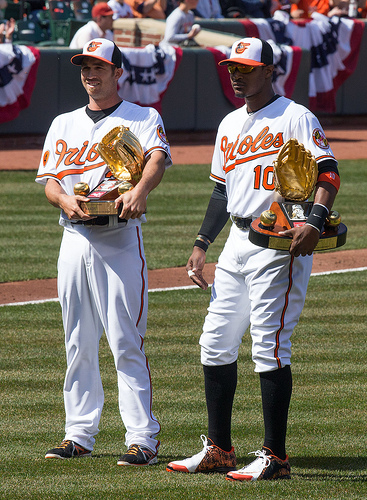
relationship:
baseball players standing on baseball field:
[33, 33, 170, 467] [4, 126, 365, 495]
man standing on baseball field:
[181, 33, 341, 482] [4, 126, 365, 495]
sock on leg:
[255, 365, 295, 454] [229, 279, 303, 481]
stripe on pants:
[139, 374, 166, 460] [60, 226, 149, 442]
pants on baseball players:
[60, 226, 149, 442] [33, 33, 170, 467]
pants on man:
[196, 218, 312, 374] [181, 33, 341, 482]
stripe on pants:
[272, 254, 296, 369] [196, 218, 312, 374]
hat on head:
[214, 35, 274, 70] [216, 37, 280, 107]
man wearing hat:
[181, 33, 341, 482] [214, 35, 274, 70]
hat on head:
[68, 34, 122, 69] [78, 62, 122, 98]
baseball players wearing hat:
[33, 33, 170, 467] [68, 34, 122, 69]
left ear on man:
[112, 65, 127, 83] [18, 34, 163, 378]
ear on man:
[264, 62, 274, 79] [165, 36, 342, 482]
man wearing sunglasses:
[181, 33, 341, 482] [224, 62, 269, 72]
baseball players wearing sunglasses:
[33, 33, 170, 467] [225, 65, 254, 74]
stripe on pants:
[133, 220, 165, 460] [131, 226, 157, 384]